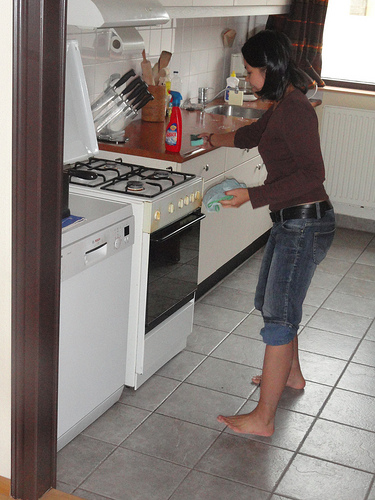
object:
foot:
[247, 370, 307, 389]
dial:
[154, 211, 161, 220]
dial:
[168, 201, 175, 214]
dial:
[177, 197, 184, 209]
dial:
[184, 195, 190, 205]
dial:
[189, 192, 196, 202]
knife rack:
[90, 84, 137, 143]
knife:
[120, 94, 155, 130]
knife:
[97, 80, 150, 134]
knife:
[92, 75, 144, 124]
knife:
[90, 69, 136, 113]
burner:
[65, 155, 142, 189]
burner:
[101, 164, 196, 199]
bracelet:
[205, 132, 216, 149]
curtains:
[265, 0, 328, 92]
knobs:
[151, 213, 208, 246]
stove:
[61, 150, 207, 395]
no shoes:
[215, 409, 277, 439]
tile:
[73, 440, 191, 499]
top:
[63, 0, 294, 29]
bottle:
[162, 88, 184, 153]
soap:
[228, 90, 244, 107]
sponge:
[201, 174, 250, 213]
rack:
[105, 24, 147, 59]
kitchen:
[53, 0, 375, 499]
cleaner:
[223, 71, 245, 106]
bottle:
[223, 68, 241, 104]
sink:
[201, 101, 271, 120]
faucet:
[190, 84, 239, 107]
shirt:
[231, 93, 331, 213]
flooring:
[53, 232, 374, 500]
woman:
[211, 21, 337, 444]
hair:
[239, 28, 308, 104]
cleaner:
[163, 87, 183, 153]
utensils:
[87, 66, 153, 137]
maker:
[222, 69, 247, 107]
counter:
[97, 93, 322, 293]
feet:
[217, 411, 277, 440]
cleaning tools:
[189, 130, 203, 147]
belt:
[268, 200, 333, 221]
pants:
[249, 198, 339, 349]